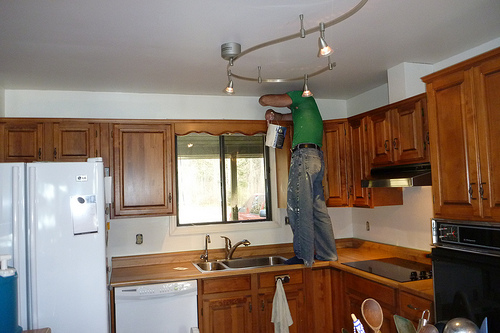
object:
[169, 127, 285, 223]
window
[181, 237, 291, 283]
sink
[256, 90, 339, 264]
man can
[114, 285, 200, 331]
door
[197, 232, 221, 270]
hose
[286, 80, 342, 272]
he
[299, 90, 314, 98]
bulb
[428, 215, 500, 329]
oven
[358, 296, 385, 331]
spoon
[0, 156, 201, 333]
white appliances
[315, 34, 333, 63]
light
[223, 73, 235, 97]
light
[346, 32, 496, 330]
wall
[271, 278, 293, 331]
rag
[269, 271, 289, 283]
handle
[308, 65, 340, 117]
ground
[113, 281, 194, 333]
dishwasher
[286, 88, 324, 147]
shirt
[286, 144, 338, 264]
jeans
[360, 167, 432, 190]
hood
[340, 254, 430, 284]
stove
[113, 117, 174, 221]
cabinet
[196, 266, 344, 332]
cabinet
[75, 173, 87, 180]
logo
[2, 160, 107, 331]
fridge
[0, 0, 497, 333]
kitchen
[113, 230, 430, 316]
counter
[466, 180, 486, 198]
knobs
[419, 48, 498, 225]
cabinet doors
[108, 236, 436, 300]
counter top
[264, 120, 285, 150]
can